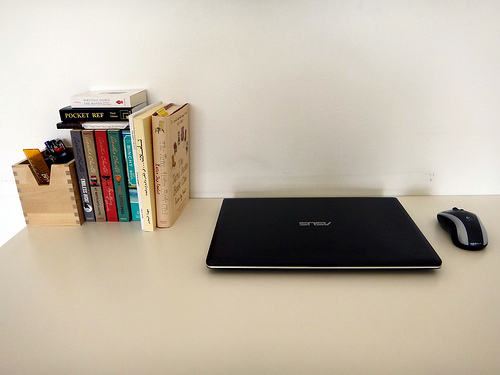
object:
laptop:
[205, 193, 439, 272]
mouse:
[437, 204, 490, 251]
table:
[0, 197, 500, 375]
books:
[121, 131, 142, 224]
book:
[69, 88, 150, 107]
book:
[60, 106, 134, 122]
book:
[83, 130, 106, 222]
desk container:
[10, 144, 79, 226]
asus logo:
[299, 220, 332, 227]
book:
[153, 104, 192, 229]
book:
[132, 112, 155, 230]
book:
[69, 130, 93, 222]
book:
[96, 129, 119, 221]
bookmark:
[155, 108, 169, 118]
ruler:
[23, 147, 49, 186]